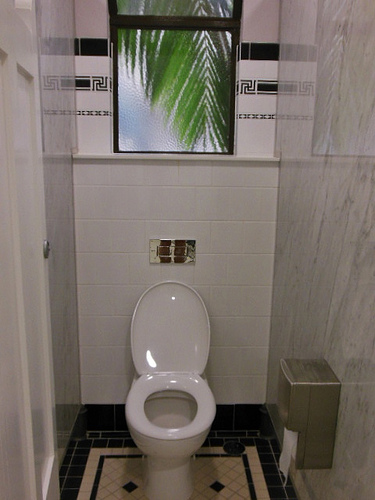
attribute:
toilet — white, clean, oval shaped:
[123, 279, 220, 500]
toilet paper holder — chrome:
[274, 355, 344, 471]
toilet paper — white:
[277, 427, 302, 492]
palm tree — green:
[118, 0, 231, 153]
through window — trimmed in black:
[104, 0, 244, 159]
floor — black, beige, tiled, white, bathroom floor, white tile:
[60, 427, 302, 500]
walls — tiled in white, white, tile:
[44, 161, 281, 405]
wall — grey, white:
[265, 0, 372, 499]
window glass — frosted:
[117, 2, 233, 150]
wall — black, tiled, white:
[38, 35, 317, 159]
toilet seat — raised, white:
[128, 279, 212, 375]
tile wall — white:
[44, 162, 283, 407]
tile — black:
[122, 479, 140, 496]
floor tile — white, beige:
[104, 466, 127, 484]